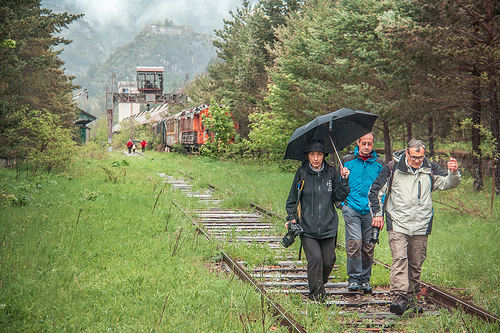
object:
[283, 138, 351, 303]
woman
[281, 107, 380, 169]
umbrella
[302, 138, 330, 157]
hat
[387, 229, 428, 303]
pants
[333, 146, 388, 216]
jacket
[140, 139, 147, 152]
person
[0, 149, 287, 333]
grass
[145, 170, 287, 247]
track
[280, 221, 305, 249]
camera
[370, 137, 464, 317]
photographer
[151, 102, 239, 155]
train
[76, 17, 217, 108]
mountain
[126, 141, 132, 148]
jacket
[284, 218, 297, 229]
hand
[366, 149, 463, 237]
jacket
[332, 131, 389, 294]
man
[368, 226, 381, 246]
camera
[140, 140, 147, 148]
red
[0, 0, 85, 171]
tree